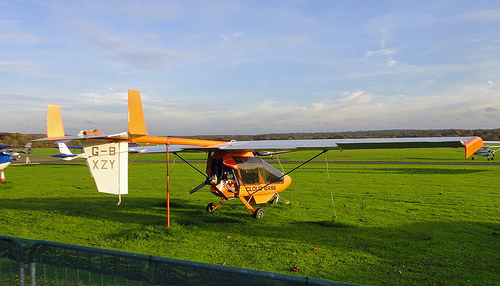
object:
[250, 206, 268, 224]
wheel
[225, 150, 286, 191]
cockpit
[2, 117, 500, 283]
field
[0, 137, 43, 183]
plane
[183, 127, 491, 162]
wing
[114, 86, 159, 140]
end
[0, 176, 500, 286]
shadow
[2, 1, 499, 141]
sky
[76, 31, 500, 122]
cloud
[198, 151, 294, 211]
cabin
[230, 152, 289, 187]
window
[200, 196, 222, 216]
gear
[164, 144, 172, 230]
pole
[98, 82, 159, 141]
tail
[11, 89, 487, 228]
helicopter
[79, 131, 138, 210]
tagging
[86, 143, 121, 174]
g-b xyz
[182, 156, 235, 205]
motor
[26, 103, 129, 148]
wing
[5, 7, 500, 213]
background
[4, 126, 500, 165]
ranges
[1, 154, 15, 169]
nose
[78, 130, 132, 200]
identification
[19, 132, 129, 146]
flap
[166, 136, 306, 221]
body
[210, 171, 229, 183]
panel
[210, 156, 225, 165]
panel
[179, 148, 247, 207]
back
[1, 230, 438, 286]
fencing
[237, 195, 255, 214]
support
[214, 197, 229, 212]
support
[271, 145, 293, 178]
line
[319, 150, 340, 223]
wire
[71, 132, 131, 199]
wing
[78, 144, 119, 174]
letters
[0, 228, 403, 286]
railing